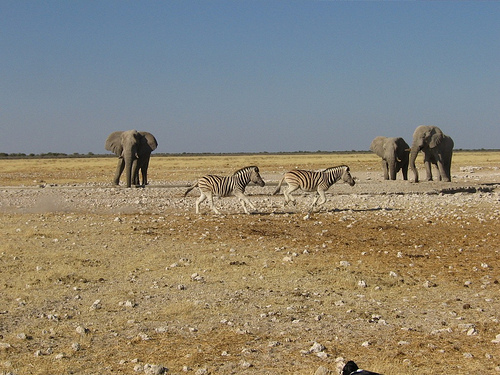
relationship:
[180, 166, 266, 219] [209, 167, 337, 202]
zebra have stripes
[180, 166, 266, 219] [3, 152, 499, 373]
zebra in desert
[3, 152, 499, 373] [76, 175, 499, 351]
desert covered in rocks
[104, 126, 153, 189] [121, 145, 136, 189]
elephant has trunk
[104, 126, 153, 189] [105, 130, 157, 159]
elephant has ears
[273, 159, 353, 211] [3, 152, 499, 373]
zebra running in desert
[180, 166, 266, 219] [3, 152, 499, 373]
zebra running on desert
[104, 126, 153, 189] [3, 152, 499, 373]
elephant standing in desert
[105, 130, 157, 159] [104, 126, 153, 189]
ears of elephant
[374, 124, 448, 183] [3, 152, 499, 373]
elephants in desert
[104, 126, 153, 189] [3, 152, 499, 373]
elephant in desert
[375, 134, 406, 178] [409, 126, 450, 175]
elephant next to elephant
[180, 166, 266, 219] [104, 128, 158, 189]
zebra and elephant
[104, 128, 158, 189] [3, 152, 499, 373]
elephant in desert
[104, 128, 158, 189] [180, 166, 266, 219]
elephant and zebra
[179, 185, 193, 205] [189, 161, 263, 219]
tail of zebra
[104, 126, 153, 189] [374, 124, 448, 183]
elephant standing next to elephants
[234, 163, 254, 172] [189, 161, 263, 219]
mane of zebra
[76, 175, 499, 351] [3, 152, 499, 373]
rocks in desert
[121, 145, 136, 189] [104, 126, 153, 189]
trunk of elephant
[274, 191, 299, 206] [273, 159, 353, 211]
legs of zebra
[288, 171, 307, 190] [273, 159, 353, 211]
dirt on zebra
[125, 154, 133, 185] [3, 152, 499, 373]
trunk touching desert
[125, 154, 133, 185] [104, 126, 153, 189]
trunk of elephant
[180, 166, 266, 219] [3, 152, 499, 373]
zebra are in desert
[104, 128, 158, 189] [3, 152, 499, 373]
elephant are in desert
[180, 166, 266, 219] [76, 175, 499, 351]
zebra on rocks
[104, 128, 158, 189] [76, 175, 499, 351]
elephant on rocks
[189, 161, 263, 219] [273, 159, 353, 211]
zebra chasing a zebra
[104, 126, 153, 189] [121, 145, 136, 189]
elephant with trunk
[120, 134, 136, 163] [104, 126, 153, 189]
head of elephant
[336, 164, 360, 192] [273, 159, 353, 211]
head of zebra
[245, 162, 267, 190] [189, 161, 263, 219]
head of zebra